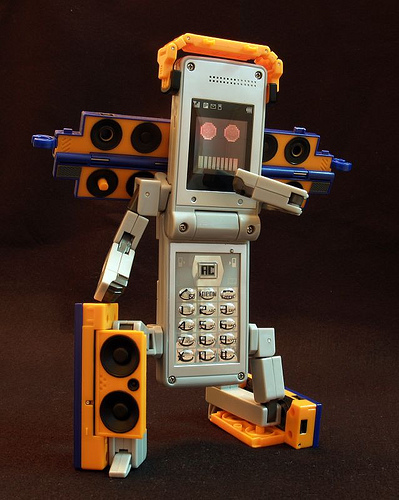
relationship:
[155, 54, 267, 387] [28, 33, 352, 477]
cell phone on robot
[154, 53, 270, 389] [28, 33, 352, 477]
phone on robot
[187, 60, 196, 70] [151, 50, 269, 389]
screw at top corner of cellphone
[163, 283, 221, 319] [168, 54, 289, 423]
button on phone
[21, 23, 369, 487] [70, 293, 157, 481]
robot phone has leg